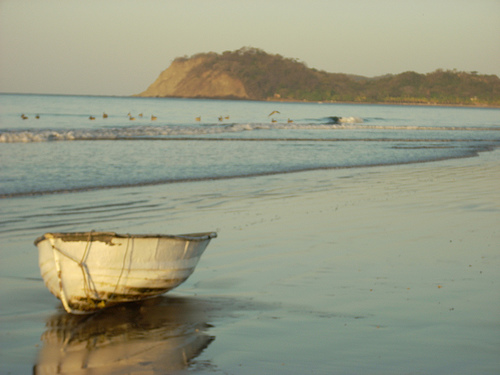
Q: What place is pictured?
A: It is a shore.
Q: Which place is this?
A: It is a shore.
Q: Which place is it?
A: It is a shore.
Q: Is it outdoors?
A: Yes, it is outdoors.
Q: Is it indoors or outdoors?
A: It is outdoors.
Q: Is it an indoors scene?
A: No, it is outdoors.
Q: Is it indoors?
A: No, it is outdoors.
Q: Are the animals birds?
A: No, there are both seagulls and birds.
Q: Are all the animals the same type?
A: No, there are both seagulls and birds.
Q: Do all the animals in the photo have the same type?
A: No, they are seagulls and birds.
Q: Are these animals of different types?
A: Yes, they are seagulls and birds.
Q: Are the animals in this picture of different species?
A: Yes, they are seagulls and birds.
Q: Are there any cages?
A: No, there are no cages.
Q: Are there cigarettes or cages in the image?
A: No, there are no cages or cigarettes.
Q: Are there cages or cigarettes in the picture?
A: No, there are no cages or cigarettes.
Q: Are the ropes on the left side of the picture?
A: Yes, the ropes are on the left of the image.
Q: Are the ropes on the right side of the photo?
A: No, the ropes are on the left of the image.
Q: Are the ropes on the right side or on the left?
A: The ropes are on the left of the image.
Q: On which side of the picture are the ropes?
A: The ropes are on the left of the image.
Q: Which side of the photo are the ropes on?
A: The ropes are on the left of the image.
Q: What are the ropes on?
A: The ropes are on the boat.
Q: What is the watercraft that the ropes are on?
A: The watercraft is a boat.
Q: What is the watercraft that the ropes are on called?
A: The watercraft is a boat.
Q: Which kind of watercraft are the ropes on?
A: The ropes are on the boat.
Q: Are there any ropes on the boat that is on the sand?
A: Yes, there are ropes on the boat.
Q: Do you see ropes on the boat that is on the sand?
A: Yes, there are ropes on the boat.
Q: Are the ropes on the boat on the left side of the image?
A: Yes, the ropes are on the boat.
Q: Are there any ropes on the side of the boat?
A: Yes, there are ropes on the side of the boat.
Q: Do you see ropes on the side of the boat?
A: Yes, there are ropes on the side of the boat.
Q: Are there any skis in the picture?
A: No, there are no skis.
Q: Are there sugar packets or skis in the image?
A: No, there are no skis or sugar packets.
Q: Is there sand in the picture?
A: Yes, there is sand.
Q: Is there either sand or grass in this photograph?
A: Yes, there is sand.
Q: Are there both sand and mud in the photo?
A: No, there is sand but no mud.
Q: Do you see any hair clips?
A: No, there are no hair clips.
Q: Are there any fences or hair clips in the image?
A: No, there are no hair clips or fences.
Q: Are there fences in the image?
A: No, there are no fences.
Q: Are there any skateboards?
A: No, there are no skateboards.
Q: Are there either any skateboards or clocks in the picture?
A: No, there are no skateboards or clocks.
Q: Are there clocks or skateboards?
A: No, there are no skateboards or clocks.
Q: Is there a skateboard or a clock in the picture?
A: No, there are no skateboards or clocks.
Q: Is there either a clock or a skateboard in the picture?
A: No, there are no skateboards or clocks.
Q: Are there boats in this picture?
A: Yes, there is a boat.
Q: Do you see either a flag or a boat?
A: Yes, there is a boat.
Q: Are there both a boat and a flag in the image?
A: No, there is a boat but no flags.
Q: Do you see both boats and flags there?
A: No, there is a boat but no flags.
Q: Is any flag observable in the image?
A: No, there are no flags.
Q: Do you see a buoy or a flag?
A: No, there are no flags or buoys.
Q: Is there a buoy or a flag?
A: No, there are no flags or buoys.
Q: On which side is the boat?
A: The boat is on the left of the image.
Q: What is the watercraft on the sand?
A: The watercraft is a boat.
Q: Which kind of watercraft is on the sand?
A: The watercraft is a boat.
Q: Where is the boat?
A: The boat is on the sand.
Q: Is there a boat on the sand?
A: Yes, there is a boat on the sand.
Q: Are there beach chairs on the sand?
A: No, there is a boat on the sand.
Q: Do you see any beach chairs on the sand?
A: No, there is a boat on the sand.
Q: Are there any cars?
A: No, there are no cars.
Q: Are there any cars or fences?
A: No, there are no cars or fences.